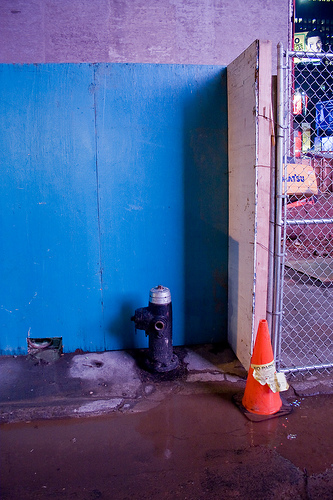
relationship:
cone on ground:
[244, 320, 288, 419] [285, 81, 310, 107]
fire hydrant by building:
[131, 286, 180, 373] [3, 0, 291, 380]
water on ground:
[0, 389, 332, 499] [11, 370, 321, 483]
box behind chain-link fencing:
[280, 164, 316, 194] [274, 43, 332, 378]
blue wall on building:
[0, 62, 228, 351] [3, 0, 291, 380]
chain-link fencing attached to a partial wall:
[274, 43, 332, 383] [227, 40, 274, 373]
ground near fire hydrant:
[0, 370, 333, 499] [131, 286, 180, 373]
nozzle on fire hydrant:
[151, 317, 165, 332] [129, 284, 184, 377]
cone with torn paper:
[241, 320, 284, 418] [249, 356, 290, 392]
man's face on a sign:
[303, 31, 324, 57] [291, 29, 330, 60]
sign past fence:
[291, 29, 330, 60] [290, 51, 331, 126]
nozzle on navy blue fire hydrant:
[131, 305, 150, 332] [121, 279, 201, 382]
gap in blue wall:
[23, 333, 65, 358] [0, 62, 228, 351]